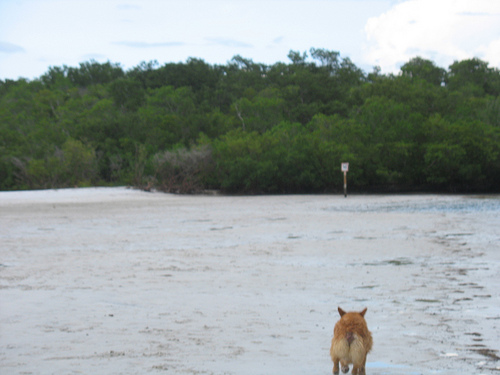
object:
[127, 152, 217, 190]
limbs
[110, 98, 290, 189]
bushes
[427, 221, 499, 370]
footprints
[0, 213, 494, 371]
sand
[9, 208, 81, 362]
beach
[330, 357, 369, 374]
legs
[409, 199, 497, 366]
waves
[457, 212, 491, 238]
water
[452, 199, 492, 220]
water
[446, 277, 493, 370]
water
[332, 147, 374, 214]
sign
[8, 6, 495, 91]
sky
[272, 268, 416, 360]
dog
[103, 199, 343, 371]
beach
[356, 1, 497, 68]
cloud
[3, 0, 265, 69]
cloud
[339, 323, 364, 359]
fur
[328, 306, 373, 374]
animal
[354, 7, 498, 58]
clouds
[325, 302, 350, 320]
ears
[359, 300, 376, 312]
ears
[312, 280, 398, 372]
dog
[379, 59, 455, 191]
tree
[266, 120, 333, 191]
tree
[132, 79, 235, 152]
tree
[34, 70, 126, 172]
tree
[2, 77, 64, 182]
tree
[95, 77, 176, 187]
tree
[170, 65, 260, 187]
tree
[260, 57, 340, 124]
tree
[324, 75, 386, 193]
tree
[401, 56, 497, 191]
tree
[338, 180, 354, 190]
post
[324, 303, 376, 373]
dog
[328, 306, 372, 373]
fox